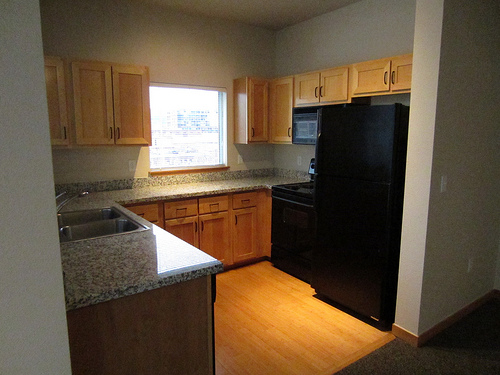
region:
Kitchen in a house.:
[22, 5, 447, 373]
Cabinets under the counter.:
[159, 200, 275, 265]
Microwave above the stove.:
[266, 83, 354, 135]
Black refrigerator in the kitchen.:
[307, 91, 406, 336]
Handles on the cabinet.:
[309, 78, 331, 110]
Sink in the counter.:
[53, 183, 159, 261]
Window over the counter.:
[127, 73, 269, 194]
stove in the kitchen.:
[259, 144, 340, 267]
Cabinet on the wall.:
[65, 40, 161, 173]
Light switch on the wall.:
[430, 165, 473, 216]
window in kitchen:
[148, 78, 237, 175]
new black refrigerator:
[312, 98, 420, 333]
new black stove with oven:
[258, 159, 325, 294]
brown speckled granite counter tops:
[50, 146, 254, 315]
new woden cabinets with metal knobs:
[128, 196, 285, 261]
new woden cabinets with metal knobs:
[45, 52, 158, 159]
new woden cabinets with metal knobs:
[237, 75, 289, 141]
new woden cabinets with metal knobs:
[294, 48, 419, 104]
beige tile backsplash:
[57, 151, 127, 174]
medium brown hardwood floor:
[218, 266, 313, 370]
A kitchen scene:
[4, 4, 489, 361]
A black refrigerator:
[308, 100, 410, 328]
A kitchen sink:
[53, 185, 154, 245]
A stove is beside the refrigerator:
[270, 157, 326, 281]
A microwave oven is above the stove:
[288, 104, 323, 147]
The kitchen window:
[147, 80, 231, 174]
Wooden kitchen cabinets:
[42, 53, 158, 151]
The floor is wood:
[208, 254, 395, 374]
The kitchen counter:
[116, 167, 271, 202]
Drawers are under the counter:
[122, 189, 262, 221]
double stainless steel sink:
[57, 206, 147, 241]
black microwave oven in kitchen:
[290, 110, 316, 142]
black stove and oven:
[272, 156, 313, 286]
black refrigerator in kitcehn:
[310, 100, 408, 332]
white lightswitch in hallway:
[437, 173, 447, 191]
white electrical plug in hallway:
[465, 255, 473, 271]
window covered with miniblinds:
[147, 84, 224, 168]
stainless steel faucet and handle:
[54, 188, 89, 218]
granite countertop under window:
[54, 166, 311, 208]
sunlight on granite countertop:
[152, 216, 217, 274]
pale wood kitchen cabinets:
[47, 52, 157, 151]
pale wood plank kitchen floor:
[229, 282, 303, 346]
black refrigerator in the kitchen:
[308, 89, 408, 322]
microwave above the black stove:
[285, 110, 322, 157]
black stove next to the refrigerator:
[269, 172, 324, 280]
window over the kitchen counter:
[141, 74, 236, 194]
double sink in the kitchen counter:
[54, 189, 151, 245]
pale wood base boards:
[390, 323, 447, 350]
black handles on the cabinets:
[105, 123, 122, 139]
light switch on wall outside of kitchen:
[434, 168, 456, 201]